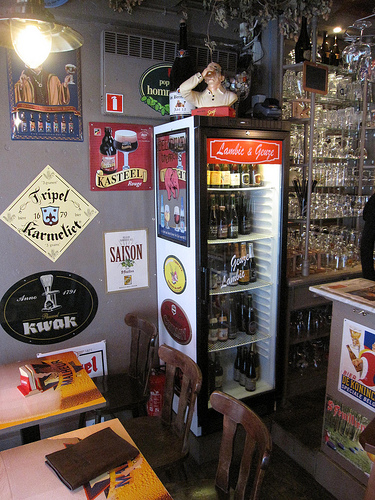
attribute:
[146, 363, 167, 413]
fire extinguisher — red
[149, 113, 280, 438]
fridge — for drinks, drink filled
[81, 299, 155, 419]
chair — brown, wooden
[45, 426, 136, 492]
notebook — brown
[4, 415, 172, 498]
table — wood, small, wooden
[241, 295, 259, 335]
bottle — beer, large, beer bottle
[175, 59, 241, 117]
sculpture — man, drinking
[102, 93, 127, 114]
sticker — fire extinguisher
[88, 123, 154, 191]
poster — kasteel, kasteel sign, white, red, saison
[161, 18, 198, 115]
bottle — large, wine bottle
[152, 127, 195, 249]
poster — magnet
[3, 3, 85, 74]
lamp — very potent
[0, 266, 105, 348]
sign — white, kwak, black, oval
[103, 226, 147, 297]
sign — brown, saison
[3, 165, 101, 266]
sign — creme colored, triple karmeliet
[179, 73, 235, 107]
shirt — white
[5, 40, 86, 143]
poster — blue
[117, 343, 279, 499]
chairs — wooden, pair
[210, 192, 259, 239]
bottles — wine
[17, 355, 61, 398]
package — napkins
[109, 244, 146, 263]
word — red, saison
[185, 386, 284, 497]
chair — wooden, brown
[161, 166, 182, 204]
elephant — pink